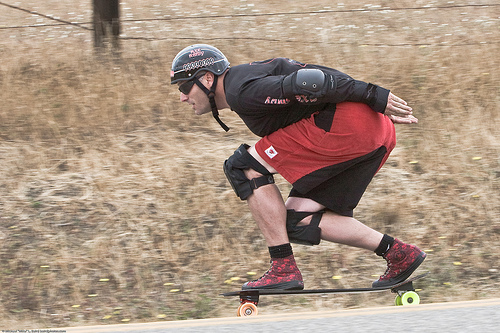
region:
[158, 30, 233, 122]
man wearing safety helmet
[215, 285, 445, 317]
skateboard with yellow and orange wheels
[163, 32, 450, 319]
kneepads on a skateboarder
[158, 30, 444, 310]
skateboarder wearing red and black shorts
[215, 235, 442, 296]
red and black high top sneakers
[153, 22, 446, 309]
man longboarding with elbow pads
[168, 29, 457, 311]
crouched man riding a longboard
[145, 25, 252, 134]
profile of a man's face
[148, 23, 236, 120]
man's profile with sunglasses and safety helment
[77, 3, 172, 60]
fence post with two wires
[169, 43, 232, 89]
the man is wearing a helmet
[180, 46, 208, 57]
the helmet has red writing on the side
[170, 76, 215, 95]
the man is wearing sunglasses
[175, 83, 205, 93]
the sunglasses are black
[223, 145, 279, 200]
he is wearing kneepads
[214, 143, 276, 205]
the knee pads are black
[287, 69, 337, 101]
he is wearing elbow pads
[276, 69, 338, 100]
the elbow pads are black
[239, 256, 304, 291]
his sneakers are black and red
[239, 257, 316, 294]
the man is wearing hitops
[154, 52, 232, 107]
black helmet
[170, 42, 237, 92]
black helmet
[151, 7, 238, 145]
black helmet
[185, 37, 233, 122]
black helmet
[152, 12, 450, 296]
man on a skateboard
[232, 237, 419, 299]
red and black shoes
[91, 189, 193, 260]
dead grass next to skater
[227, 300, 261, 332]
wheel on the board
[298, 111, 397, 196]
red and black shorts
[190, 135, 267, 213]
knee pad on the man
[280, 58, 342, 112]
elbow pad on the man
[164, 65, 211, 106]
glasses on the man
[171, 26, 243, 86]
helmet on the man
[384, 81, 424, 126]
hands of the man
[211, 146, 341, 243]
Black protective knee pads.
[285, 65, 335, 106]
Black protective elbow pads.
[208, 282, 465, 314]
Skateboard with peach and white wheels.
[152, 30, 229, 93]
Black protective helmet with strap.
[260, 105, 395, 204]
Black and red shorts.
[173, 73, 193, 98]
Protective sunglasses/goggles.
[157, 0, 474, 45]
Wire fence in field.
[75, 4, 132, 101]
Fence pole in field.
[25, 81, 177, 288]
Brown foliage surrounding skateboarder.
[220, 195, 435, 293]
Black and red athletic shoes.